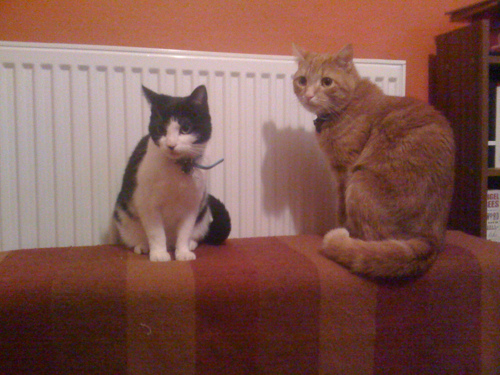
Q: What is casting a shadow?
A: Orange cat.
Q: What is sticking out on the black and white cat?
A: Blue collar.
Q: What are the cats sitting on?
A: The ottoman.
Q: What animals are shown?
A: Cats.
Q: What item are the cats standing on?
A: A ottoman.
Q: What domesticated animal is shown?
A: A cat.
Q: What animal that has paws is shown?
A: A cat.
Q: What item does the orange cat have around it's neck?
A: A collar.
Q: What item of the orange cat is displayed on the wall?
A: A shadow.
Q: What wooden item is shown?
A: A bookshelf.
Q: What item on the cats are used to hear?
A: Ears.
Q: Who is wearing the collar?
A: Orange cat.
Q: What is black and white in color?
A: A cat.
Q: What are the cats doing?
A: Sitting.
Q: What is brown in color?
A: A cupboard.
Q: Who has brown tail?
A: The cat.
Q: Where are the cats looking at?
A: In the camera.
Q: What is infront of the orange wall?
A: A white wall.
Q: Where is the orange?
A: Cat.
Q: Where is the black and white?
A: Cat.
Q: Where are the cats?
A: Bench.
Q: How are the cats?
A: Sitting.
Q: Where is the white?
A: On vent.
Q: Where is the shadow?
A: Back of bench.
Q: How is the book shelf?
A: Wooden.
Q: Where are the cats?
A: On bench.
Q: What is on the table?
A: Cat.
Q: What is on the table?
A: Brown cat.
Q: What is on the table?
A: Cats.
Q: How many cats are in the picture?
A: Two.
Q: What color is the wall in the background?
A: Orange.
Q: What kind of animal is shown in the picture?
A: Cats.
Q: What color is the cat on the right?
A: Orange.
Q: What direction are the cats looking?
A: To their right.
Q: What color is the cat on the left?
A: Black and white.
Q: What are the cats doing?
A: Sitting.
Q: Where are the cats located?
A: On ottoman.